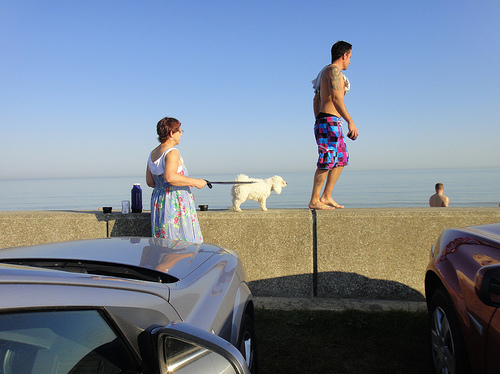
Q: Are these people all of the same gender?
A: No, they are both male and female.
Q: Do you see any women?
A: Yes, there is a woman.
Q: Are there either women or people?
A: Yes, there is a woman.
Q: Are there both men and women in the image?
A: Yes, there are both a woman and a man.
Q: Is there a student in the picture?
A: No, there are no students.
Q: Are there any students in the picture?
A: No, there are no students.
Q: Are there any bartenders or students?
A: No, there are no students or bartenders.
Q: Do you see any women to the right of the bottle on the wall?
A: Yes, there is a woman to the right of the bottle.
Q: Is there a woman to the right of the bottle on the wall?
A: Yes, there is a woman to the right of the bottle.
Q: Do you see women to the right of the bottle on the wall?
A: Yes, there is a woman to the right of the bottle.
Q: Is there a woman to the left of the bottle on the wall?
A: No, the woman is to the right of the bottle.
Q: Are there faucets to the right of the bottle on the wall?
A: No, there is a woman to the right of the bottle.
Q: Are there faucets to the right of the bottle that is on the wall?
A: No, there is a woman to the right of the bottle.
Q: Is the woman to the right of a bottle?
A: Yes, the woman is to the right of a bottle.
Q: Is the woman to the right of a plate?
A: No, the woman is to the right of a bottle.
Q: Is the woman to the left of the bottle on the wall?
A: No, the woman is to the right of the bottle.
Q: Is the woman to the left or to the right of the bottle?
A: The woman is to the right of the bottle.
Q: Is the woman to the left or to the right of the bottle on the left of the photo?
A: The woman is to the right of the bottle.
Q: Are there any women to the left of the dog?
A: Yes, there is a woman to the left of the dog.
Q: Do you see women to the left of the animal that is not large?
A: Yes, there is a woman to the left of the dog.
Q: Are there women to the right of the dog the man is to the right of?
A: No, the woman is to the left of the dog.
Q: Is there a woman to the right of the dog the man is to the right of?
A: No, the woman is to the left of the dog.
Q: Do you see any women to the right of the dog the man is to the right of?
A: No, the woman is to the left of the dog.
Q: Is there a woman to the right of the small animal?
A: No, the woman is to the left of the dog.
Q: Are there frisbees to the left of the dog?
A: No, there is a woman to the left of the dog.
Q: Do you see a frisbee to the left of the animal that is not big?
A: No, there is a woman to the left of the dog.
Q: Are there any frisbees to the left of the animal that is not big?
A: No, there is a woman to the left of the dog.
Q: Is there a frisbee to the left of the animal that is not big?
A: No, there is a woman to the left of the dog.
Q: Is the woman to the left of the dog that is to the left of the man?
A: Yes, the woman is to the left of the dog.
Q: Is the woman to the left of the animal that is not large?
A: Yes, the woman is to the left of the dog.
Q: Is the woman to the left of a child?
A: No, the woman is to the left of the dog.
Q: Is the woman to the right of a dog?
A: No, the woman is to the left of a dog.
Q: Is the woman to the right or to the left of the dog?
A: The woman is to the left of the dog.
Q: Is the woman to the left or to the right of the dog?
A: The woman is to the left of the dog.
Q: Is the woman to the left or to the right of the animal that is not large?
A: The woman is to the left of the dog.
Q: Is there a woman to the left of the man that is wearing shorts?
A: Yes, there is a woman to the left of the man.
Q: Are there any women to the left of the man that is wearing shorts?
A: Yes, there is a woman to the left of the man.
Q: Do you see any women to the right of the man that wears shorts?
A: No, the woman is to the left of the man.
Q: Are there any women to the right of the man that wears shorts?
A: No, the woman is to the left of the man.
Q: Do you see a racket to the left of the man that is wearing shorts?
A: No, there is a woman to the left of the man.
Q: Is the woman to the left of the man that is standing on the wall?
A: Yes, the woman is to the left of the man.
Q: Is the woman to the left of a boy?
A: No, the woman is to the left of the man.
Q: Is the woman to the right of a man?
A: No, the woman is to the left of a man.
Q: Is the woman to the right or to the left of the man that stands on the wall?
A: The woman is to the left of the man.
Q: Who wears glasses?
A: The woman wears glasses.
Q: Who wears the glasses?
A: The woman wears glasses.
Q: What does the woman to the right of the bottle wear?
A: The woman wears glasses.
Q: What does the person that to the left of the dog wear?
A: The woman wears glasses.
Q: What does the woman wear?
A: The woman wears glasses.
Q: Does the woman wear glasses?
A: Yes, the woman wears glasses.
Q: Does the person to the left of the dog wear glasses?
A: Yes, the woman wears glasses.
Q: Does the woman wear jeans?
A: No, the woman wears glasses.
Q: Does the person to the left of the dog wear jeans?
A: No, the woman wears glasses.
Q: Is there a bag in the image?
A: No, there are no bags.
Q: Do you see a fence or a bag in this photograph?
A: No, there are no bags or fences.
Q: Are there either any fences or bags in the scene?
A: No, there are no bags or fences.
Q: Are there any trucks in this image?
A: No, there are no trucks.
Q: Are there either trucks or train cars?
A: No, there are no trucks or train cars.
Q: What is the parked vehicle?
A: The vehicle is a car.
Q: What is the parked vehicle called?
A: The vehicle is a car.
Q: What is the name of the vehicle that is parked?
A: The vehicle is a car.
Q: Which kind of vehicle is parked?
A: The vehicle is a car.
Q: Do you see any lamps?
A: No, there are no lamps.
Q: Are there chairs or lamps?
A: No, there are no lamps or chairs.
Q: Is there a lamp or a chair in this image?
A: No, there are no lamps or chairs.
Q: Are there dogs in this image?
A: Yes, there is a dog.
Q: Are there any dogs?
A: Yes, there is a dog.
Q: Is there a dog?
A: Yes, there is a dog.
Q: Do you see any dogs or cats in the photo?
A: Yes, there is a dog.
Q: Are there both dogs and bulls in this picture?
A: No, there is a dog but no bulls.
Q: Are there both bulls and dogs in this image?
A: No, there is a dog but no bulls.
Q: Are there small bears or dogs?
A: Yes, there is a small dog.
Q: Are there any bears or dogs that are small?
A: Yes, the dog is small.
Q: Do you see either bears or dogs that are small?
A: Yes, the dog is small.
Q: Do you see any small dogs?
A: Yes, there is a small dog.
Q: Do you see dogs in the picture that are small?
A: Yes, there is a dog that is small.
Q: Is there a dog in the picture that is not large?
A: Yes, there is a small dog.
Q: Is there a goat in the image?
A: No, there are no goats.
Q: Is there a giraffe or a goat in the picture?
A: No, there are no goats or giraffes.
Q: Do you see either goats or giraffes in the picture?
A: No, there are no goats or giraffes.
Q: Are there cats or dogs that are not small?
A: No, there is a dog but it is small.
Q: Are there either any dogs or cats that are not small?
A: No, there is a dog but it is small.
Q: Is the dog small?
A: Yes, the dog is small.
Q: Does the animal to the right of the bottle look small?
A: Yes, the dog is small.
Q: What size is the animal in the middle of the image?
A: The dog is small.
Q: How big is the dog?
A: The dog is small.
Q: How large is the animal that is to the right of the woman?
A: The dog is small.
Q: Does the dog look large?
A: No, the dog is small.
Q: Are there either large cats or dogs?
A: No, there is a dog but it is small.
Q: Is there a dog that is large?
A: No, there is a dog but it is small.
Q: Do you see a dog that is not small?
A: No, there is a dog but it is small.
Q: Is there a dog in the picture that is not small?
A: No, there is a dog but it is small.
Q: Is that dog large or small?
A: The dog is small.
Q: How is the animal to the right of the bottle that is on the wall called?
A: The animal is a dog.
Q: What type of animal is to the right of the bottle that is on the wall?
A: The animal is a dog.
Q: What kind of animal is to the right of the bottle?
A: The animal is a dog.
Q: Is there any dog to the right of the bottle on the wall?
A: Yes, there is a dog to the right of the bottle.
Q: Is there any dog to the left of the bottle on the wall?
A: No, the dog is to the right of the bottle.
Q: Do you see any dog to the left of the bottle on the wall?
A: No, the dog is to the right of the bottle.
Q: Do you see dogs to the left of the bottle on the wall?
A: No, the dog is to the right of the bottle.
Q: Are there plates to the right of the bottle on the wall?
A: No, there is a dog to the right of the bottle.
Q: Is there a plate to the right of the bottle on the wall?
A: No, there is a dog to the right of the bottle.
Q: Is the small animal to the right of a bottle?
A: Yes, the dog is to the right of a bottle.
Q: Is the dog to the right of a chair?
A: No, the dog is to the right of a bottle.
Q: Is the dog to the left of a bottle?
A: No, the dog is to the right of a bottle.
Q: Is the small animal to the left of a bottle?
A: No, the dog is to the right of a bottle.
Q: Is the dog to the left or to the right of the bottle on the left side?
A: The dog is to the right of the bottle.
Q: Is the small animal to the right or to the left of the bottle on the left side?
A: The dog is to the right of the bottle.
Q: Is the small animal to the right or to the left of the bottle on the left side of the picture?
A: The dog is to the right of the bottle.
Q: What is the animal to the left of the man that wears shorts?
A: The animal is a dog.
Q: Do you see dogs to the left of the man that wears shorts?
A: Yes, there is a dog to the left of the man.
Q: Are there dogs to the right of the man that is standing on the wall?
A: No, the dog is to the left of the man.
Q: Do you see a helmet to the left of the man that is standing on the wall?
A: No, there is a dog to the left of the man.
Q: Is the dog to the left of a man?
A: Yes, the dog is to the left of a man.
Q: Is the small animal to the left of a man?
A: Yes, the dog is to the left of a man.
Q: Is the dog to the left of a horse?
A: No, the dog is to the left of a man.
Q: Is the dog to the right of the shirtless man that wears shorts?
A: No, the dog is to the left of the man.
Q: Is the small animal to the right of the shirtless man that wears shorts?
A: No, the dog is to the left of the man.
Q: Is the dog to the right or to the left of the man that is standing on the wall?
A: The dog is to the left of the man.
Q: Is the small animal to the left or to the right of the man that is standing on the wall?
A: The dog is to the left of the man.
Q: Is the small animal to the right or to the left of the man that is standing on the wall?
A: The dog is to the left of the man.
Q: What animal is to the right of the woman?
A: The animal is a dog.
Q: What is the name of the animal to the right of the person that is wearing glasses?
A: The animal is a dog.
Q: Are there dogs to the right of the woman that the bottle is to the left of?
A: Yes, there is a dog to the right of the woman.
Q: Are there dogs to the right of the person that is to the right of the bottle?
A: Yes, there is a dog to the right of the woman.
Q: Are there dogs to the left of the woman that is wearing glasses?
A: No, the dog is to the right of the woman.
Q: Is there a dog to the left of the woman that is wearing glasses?
A: No, the dog is to the right of the woman.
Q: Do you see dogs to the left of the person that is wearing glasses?
A: No, the dog is to the right of the woman.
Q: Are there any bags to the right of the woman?
A: No, there is a dog to the right of the woman.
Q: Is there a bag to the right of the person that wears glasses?
A: No, there is a dog to the right of the woman.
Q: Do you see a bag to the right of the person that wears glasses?
A: No, there is a dog to the right of the woman.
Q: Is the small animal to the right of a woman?
A: Yes, the dog is to the right of a woman.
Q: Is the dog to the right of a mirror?
A: No, the dog is to the right of a woman.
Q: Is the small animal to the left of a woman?
A: No, the dog is to the right of a woman.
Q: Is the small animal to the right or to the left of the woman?
A: The dog is to the right of the woman.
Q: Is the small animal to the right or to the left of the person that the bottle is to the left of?
A: The dog is to the right of the woman.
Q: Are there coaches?
A: No, there are no coaches.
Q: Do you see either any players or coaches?
A: No, there are no coaches or players.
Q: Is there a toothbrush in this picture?
A: No, there are no toothbrushes.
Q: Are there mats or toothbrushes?
A: No, there are no toothbrushes or mats.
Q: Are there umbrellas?
A: No, there are no umbrellas.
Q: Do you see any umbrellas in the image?
A: No, there are no umbrellas.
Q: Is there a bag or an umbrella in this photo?
A: No, there are no umbrellas or bags.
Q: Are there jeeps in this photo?
A: No, there are no jeeps.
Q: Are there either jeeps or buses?
A: No, there are no jeeps or buses.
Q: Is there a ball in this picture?
A: No, there are no balls.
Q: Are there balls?
A: No, there are no balls.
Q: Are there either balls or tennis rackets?
A: No, there are no balls or tennis rackets.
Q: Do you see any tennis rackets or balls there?
A: No, there are no balls or tennis rackets.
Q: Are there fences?
A: No, there are no fences.